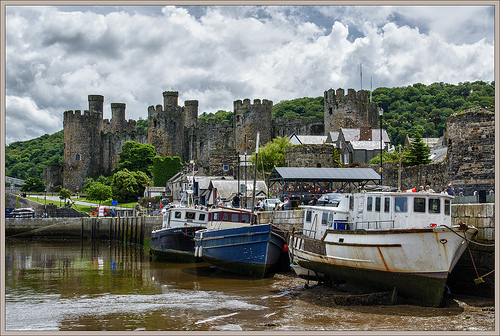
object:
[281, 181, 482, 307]
boat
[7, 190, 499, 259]
dock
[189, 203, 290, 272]
boat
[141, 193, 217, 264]
boat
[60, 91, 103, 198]
tower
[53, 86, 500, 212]
castle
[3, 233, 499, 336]
water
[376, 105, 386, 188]
light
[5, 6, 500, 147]
sky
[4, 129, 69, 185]
hillside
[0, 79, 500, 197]
hill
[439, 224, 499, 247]
rope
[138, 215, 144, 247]
post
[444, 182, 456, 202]
onlooker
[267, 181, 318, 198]
streamer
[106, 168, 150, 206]
foliage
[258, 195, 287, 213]
vehicle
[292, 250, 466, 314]
bottom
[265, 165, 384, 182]
roof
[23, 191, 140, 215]
road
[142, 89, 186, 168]
tower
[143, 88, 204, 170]
group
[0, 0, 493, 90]
cloud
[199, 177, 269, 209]
building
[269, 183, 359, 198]
flag